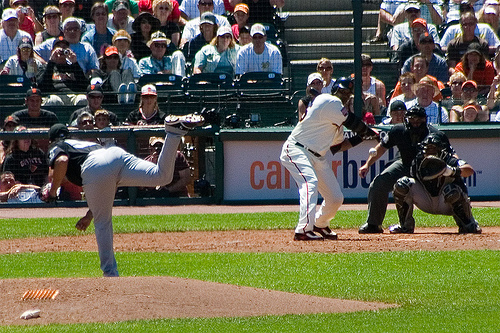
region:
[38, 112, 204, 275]
Pitcher throwing the baseball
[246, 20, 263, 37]
White cap on man's head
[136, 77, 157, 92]
Woman with white and red cap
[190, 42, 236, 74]
Woman wearing light blue top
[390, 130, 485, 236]
Catcher kneeling to catch the baseball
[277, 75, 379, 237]
Batter getting ready to strike baseball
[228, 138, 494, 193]
White, orange and black advertisement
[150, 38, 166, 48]
Sunglasses on man's face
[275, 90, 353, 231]
White uniform worn by batter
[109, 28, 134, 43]
Yellow hat on man's head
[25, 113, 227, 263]
He is throwing the ball.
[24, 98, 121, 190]
He has a black jersey on.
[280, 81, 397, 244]
He is hitting the ball.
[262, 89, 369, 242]
He is wearing a white shirt.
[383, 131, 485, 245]
He is catching the ball.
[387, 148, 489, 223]
His mit is open.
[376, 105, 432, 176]
The umpire is behind the catcher.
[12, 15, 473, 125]
The fans are watching.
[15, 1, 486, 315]
They are playing baseball.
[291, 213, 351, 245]
His shoes are black.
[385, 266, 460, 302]
the field is green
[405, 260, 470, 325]
they are playing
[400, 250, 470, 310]
softball is a sport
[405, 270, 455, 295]
people are watching softball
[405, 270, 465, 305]
audience in softball sport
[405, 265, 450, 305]
the guys is falling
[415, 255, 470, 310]
the guys is wearing white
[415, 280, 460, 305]
the grass is green and cool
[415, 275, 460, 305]
the grass is beautiful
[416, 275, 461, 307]
the grass is nice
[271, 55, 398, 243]
the man swinging the bat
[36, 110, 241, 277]
the man is throwing the ball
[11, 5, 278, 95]
the spectators in the stands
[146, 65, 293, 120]
the empty seats in the stands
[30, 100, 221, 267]
the man on the pitchers mound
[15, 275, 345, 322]
the mound is made of dirt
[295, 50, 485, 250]
the men at home plate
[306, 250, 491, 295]
the grass on the field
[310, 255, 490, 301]
the grass is well cut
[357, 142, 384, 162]
the ball is in mid air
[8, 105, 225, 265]
a baseball player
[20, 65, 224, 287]
a baseball player throwing a ball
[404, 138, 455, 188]
a baseball glove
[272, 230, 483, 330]
green grass at a baseball field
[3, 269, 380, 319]
dirt on a baseball field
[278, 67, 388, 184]
a baseball player wearing a white shirt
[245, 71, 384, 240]
a baseball player wearing white pants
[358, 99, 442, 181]
a baseball player wearing a black shirt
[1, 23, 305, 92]
people watching a baseball game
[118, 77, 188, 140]
a person wearing a hat